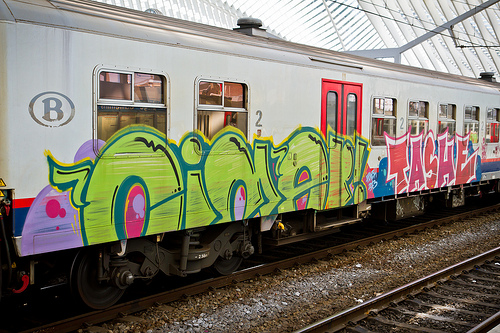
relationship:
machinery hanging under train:
[8, 259, 33, 314] [1, 0, 498, 324]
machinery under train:
[8, 259, 33, 314] [5, 76, 499, 296]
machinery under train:
[5, 261, 36, 302] [2, 1, 497, 269]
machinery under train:
[8, 259, 33, 314] [1, 0, 498, 324]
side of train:
[6, 1, 498, 265] [1, 0, 498, 324]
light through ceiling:
[251, 2, 359, 43] [92, 0, 498, 79]